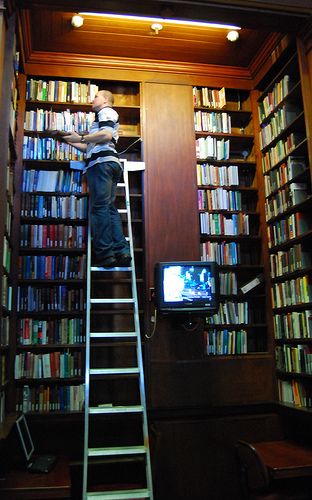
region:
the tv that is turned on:
[150, 252, 219, 316]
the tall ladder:
[74, 151, 156, 497]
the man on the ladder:
[59, 85, 131, 270]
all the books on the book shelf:
[10, 45, 310, 417]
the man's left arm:
[64, 106, 114, 146]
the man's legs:
[83, 154, 132, 268]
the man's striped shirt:
[82, 109, 123, 166]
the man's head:
[89, 88, 113, 110]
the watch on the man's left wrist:
[78, 133, 85, 144]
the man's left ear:
[102, 93, 110, 103]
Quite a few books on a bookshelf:
[189, 84, 307, 259]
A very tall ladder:
[79, 156, 155, 498]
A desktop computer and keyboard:
[14, 412, 61, 476]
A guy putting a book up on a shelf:
[43, 72, 139, 270]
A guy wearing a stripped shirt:
[74, 86, 139, 278]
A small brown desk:
[249, 429, 310, 484]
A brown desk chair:
[227, 433, 272, 496]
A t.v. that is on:
[152, 253, 220, 318]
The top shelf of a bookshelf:
[183, 83, 252, 110]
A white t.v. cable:
[142, 306, 165, 340]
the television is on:
[136, 248, 226, 317]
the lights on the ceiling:
[73, 12, 251, 45]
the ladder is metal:
[68, 159, 149, 495]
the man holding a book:
[45, 87, 135, 261]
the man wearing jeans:
[71, 87, 136, 252]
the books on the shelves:
[199, 94, 252, 334]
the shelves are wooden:
[159, 85, 263, 328]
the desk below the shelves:
[252, 435, 310, 467]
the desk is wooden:
[236, 430, 308, 489]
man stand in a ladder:
[49, 84, 159, 279]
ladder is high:
[72, 155, 160, 499]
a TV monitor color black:
[152, 248, 231, 340]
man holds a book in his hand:
[34, 79, 125, 175]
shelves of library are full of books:
[2, 32, 310, 393]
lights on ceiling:
[61, 5, 246, 46]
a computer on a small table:
[7, 409, 60, 481]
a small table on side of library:
[223, 421, 310, 489]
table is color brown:
[242, 429, 310, 487]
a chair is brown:
[215, 433, 274, 498]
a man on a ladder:
[39, 65, 172, 316]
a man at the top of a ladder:
[34, 69, 202, 295]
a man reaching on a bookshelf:
[22, 78, 180, 285]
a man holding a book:
[29, 62, 171, 290]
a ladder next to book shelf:
[59, 140, 180, 497]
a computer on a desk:
[11, 405, 70, 497]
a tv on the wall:
[140, 244, 242, 334]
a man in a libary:
[27, 73, 181, 275]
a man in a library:
[43, 75, 198, 284]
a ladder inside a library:
[27, 106, 187, 498]